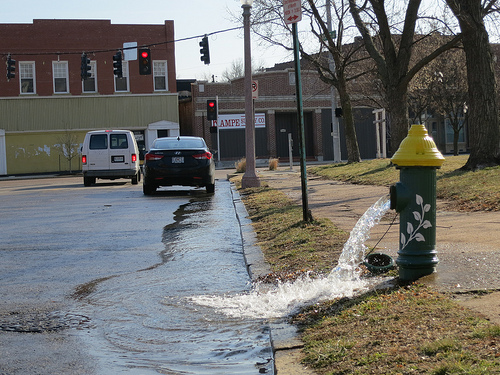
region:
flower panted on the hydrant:
[386, 190, 433, 253]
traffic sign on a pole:
[281, 3, 301, 23]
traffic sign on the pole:
[246, 73, 258, 104]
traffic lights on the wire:
[74, 35, 219, 83]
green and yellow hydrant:
[357, 106, 467, 262]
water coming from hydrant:
[309, 183, 396, 299]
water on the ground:
[165, 255, 266, 332]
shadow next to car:
[88, 182, 138, 224]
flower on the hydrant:
[390, 193, 442, 256]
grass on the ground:
[338, 308, 423, 364]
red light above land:
[131, 40, 163, 82]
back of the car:
[144, 136, 214, 195]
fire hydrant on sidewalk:
[382, 120, 447, 287]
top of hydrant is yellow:
[386, 120, 446, 172]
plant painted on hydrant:
[389, 193, 431, 255]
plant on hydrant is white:
[393, 192, 433, 255]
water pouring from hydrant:
[326, 191, 404, 285]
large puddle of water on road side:
[70, 175, 278, 372]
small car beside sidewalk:
[141, 130, 218, 200]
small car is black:
[137, 132, 218, 202]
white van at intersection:
[76, 124, 144, 187]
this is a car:
[131, 130, 233, 217]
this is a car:
[71, 115, 161, 206]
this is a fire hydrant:
[355, 111, 475, 312]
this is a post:
[221, 15, 282, 198]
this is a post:
[280, 31, 347, 243]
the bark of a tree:
[370, 41, 440, 183]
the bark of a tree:
[455, 15, 490, 175]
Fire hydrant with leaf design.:
[393, 119, 445, 278]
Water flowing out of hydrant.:
[180, 116, 447, 309]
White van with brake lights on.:
[71, 125, 141, 181]